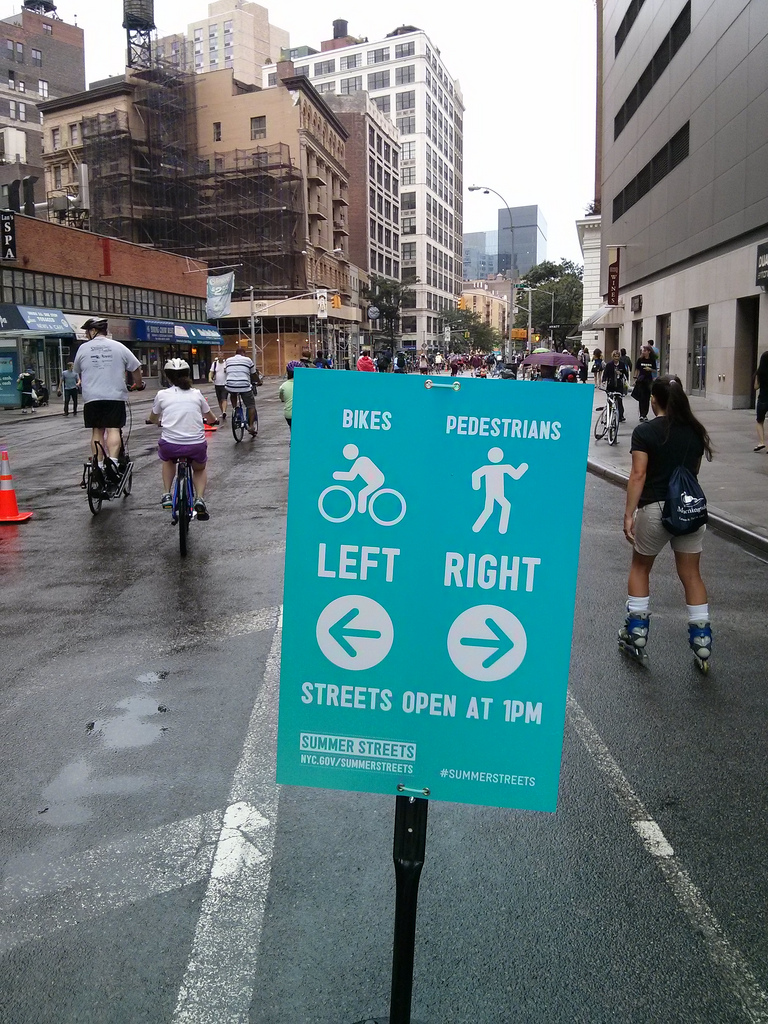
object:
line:
[561, 681, 761, 1017]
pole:
[388, 789, 434, 1024]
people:
[212, 317, 272, 476]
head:
[637, 347, 701, 428]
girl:
[606, 332, 736, 699]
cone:
[2, 446, 29, 518]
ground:
[2, 341, 760, 1024]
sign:
[271, 353, 606, 845]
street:
[4, 349, 768, 1023]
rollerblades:
[612, 599, 670, 680]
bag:
[655, 462, 721, 545]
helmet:
[158, 351, 196, 384]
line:
[169, 588, 289, 1023]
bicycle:
[309, 464, 417, 535]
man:
[53, 287, 151, 539]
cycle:
[77, 451, 115, 532]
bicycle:
[141, 409, 225, 576]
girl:
[147, 309, 222, 545]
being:
[311, 429, 412, 535]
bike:
[221, 370, 271, 456]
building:
[0, 0, 768, 424]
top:
[0, 0, 490, 101]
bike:
[58, 369, 150, 526]